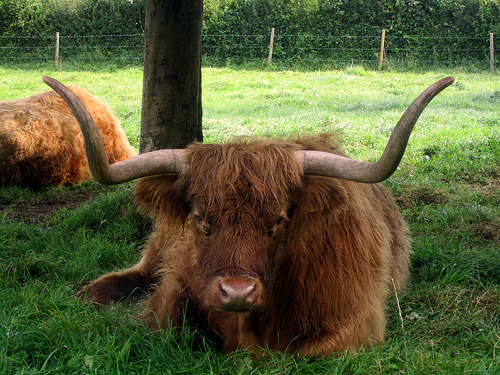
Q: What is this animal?
A: A yak.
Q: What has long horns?
A: Yak.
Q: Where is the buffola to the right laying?
A: On the ground.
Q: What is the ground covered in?
A: Grass.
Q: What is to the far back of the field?
A: A fence.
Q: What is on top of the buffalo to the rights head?
A: Horns.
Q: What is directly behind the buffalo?
A: A tree trunk.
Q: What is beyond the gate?
A: Trees.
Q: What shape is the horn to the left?
A: L shaped.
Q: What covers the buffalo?
A: Fur.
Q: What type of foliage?
A: Tree.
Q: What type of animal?
A: Cow.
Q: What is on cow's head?
A: Horns.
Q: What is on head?
A: Horns.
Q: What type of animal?
A: Cow.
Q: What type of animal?
A: Cow.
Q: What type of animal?
A: Cow.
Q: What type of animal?
A: Cow.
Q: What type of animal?
A: Cow.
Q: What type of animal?
A: Cow.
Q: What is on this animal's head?
A: Horns.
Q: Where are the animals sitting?
A: In a field.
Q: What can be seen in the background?
A: Trees.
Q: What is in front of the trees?
A: A fence.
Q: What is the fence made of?
A: Wood and wire.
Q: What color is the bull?
A: Brown.